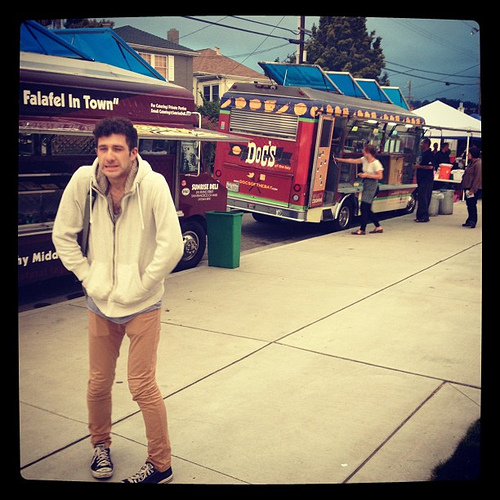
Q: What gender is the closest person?
A: Male.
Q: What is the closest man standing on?
A: Sidewalk.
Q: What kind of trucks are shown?
A: Food trucks.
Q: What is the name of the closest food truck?
A: Falafel In Town.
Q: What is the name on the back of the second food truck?
A: Doc's.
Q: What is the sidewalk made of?
A: Concrete.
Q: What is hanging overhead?
A: Power lines.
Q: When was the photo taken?
A: During the daytime.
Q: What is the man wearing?
A: A sweatshirt.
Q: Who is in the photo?
A: A man.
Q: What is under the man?
A: The cement.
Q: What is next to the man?
A: Vehicles.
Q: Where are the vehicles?
A: Next to the man.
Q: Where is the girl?
A: Next to a red truck.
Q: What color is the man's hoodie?
A: White.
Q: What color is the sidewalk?
A: Grey.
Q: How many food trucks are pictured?
A: Two.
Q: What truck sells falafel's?
A: The purple one.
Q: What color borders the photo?
A: Black.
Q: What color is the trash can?
A: Green.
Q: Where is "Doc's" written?
A: On the red truck.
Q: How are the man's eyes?
A: Closed.